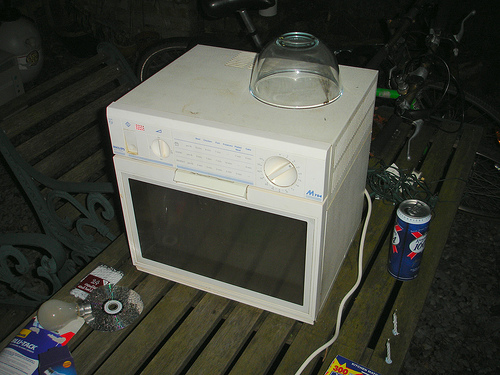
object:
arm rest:
[1, 140, 116, 258]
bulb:
[36, 293, 93, 330]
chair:
[100, 289, 270, 375]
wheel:
[400, 75, 500, 223]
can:
[385, 198, 436, 283]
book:
[68, 266, 123, 302]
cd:
[78, 282, 144, 333]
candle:
[391, 308, 399, 337]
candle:
[383, 338, 393, 364]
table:
[0, 39, 485, 374]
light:
[36, 296, 120, 332]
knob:
[261, 154, 301, 188]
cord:
[294, 187, 371, 375]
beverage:
[385, 197, 434, 282]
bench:
[3, 44, 134, 251]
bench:
[429, 145, 465, 192]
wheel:
[134, 43, 216, 84]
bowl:
[248, 25, 349, 110]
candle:
[391, 308, 403, 336]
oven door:
[109, 151, 323, 326]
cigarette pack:
[67, 263, 127, 305]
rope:
[390, 308, 402, 338]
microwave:
[103, 41, 381, 326]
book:
[0, 310, 84, 375]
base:
[80, 303, 95, 316]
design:
[406, 227, 429, 260]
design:
[390, 220, 404, 254]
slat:
[376, 108, 481, 373]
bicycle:
[128, 0, 499, 222]